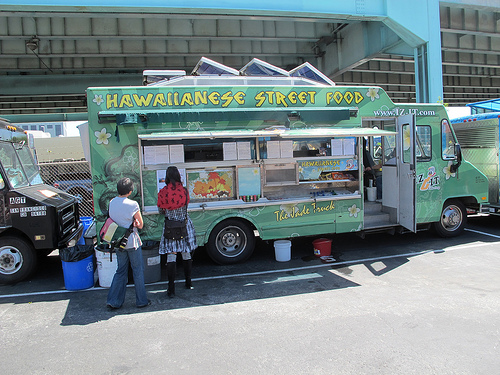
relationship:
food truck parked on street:
[80, 57, 500, 262] [1, 217, 499, 373]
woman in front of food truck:
[155, 166, 198, 296] [80, 57, 500, 262]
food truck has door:
[80, 57, 500, 262] [361, 115, 418, 234]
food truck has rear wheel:
[80, 57, 500, 262] [204, 217, 258, 263]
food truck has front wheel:
[80, 57, 500, 262] [434, 199, 466, 238]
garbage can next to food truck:
[59, 245, 98, 290] [80, 57, 500, 262]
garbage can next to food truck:
[92, 244, 124, 287] [80, 57, 500, 262]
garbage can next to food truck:
[139, 240, 164, 283] [80, 57, 500, 262]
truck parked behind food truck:
[1, 119, 83, 281] [80, 57, 500, 262]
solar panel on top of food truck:
[144, 69, 185, 85] [80, 57, 500, 262]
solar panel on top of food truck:
[191, 57, 238, 77] [80, 57, 500, 262]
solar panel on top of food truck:
[239, 60, 288, 80] [80, 57, 500, 262]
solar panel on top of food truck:
[288, 61, 336, 87] [80, 57, 500, 262]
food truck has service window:
[80, 57, 500, 262] [188, 168, 237, 204]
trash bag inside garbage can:
[57, 245, 94, 262] [59, 245, 98, 290]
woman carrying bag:
[155, 166, 198, 296] [163, 217, 188, 242]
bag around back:
[163, 217, 188, 242] [161, 186, 188, 216]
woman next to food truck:
[155, 166, 198, 296] [80, 57, 500, 262]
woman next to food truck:
[95, 178, 153, 309] [80, 57, 500, 262]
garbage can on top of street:
[92, 244, 124, 287] [1, 217, 499, 373]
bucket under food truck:
[274, 239, 292, 262] [80, 57, 500, 262]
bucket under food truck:
[311, 238, 333, 257] [80, 57, 500, 262]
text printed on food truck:
[103, 91, 364, 108] [80, 57, 500, 262]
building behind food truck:
[37, 135, 91, 183] [80, 57, 500, 262]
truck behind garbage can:
[1, 119, 83, 281] [59, 245, 98, 290]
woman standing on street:
[155, 166, 198, 296] [1, 217, 499, 373]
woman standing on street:
[95, 178, 153, 309] [1, 217, 499, 373]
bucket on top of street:
[274, 239, 292, 262] [1, 217, 499, 373]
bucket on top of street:
[311, 238, 333, 257] [1, 217, 499, 373]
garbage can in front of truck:
[59, 245, 98, 290] [1, 119, 83, 281]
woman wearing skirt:
[155, 166, 198, 296] [157, 221, 199, 254]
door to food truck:
[361, 115, 418, 234] [80, 57, 500, 262]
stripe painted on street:
[0, 239, 498, 315] [1, 217, 499, 373]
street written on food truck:
[254, 90, 318, 107] [80, 57, 500, 262]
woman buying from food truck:
[155, 166, 198, 296] [80, 57, 500, 262]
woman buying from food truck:
[95, 178, 153, 309] [80, 57, 500, 262]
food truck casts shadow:
[80, 57, 500, 262] [61, 232, 497, 322]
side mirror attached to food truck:
[450, 143, 462, 171] [80, 57, 500, 262]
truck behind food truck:
[1, 119, 83, 281] [80, 57, 500, 262]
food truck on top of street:
[80, 57, 500, 262] [1, 217, 499, 373]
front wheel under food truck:
[434, 199, 466, 238] [80, 57, 500, 262]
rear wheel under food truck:
[204, 217, 258, 263] [80, 57, 500, 262]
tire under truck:
[0, 237, 37, 285] [1, 119, 83, 281]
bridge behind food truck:
[0, 3, 500, 123] [80, 57, 500, 262]